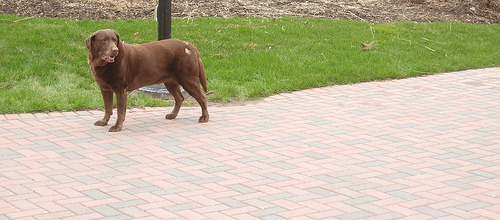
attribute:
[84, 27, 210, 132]
dog — brown, standing, alone, red, looking, golden retriever, large, furry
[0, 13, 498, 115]
grass — green, freshly cut, border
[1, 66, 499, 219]
ground — bricked, brick, sidewalk, red, black, stone, pathway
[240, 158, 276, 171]
brick — red, rectangular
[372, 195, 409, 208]
brick — red, rectangular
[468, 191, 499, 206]
brick — red, rectangular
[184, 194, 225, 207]
brick — red, rectangular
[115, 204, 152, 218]
brick — red, rectangular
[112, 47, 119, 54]
nose — brown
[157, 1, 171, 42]
pole — black, grey, metal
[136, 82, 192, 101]
bottom — silver, gray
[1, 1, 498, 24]
grass — brown, dry, dried, dead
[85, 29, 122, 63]
head — turned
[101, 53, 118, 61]
mouth — open, pink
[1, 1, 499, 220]
scene — daytime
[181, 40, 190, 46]
spot — white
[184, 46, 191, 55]
spot — white